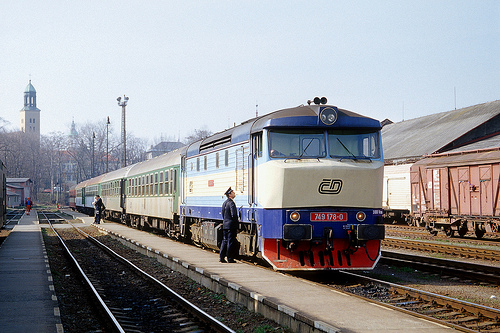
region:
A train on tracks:
[74, 99, 390, 280]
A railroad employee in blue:
[215, 181, 247, 270]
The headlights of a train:
[282, 196, 371, 227]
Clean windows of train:
[267, 120, 381, 167]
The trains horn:
[302, 91, 328, 109]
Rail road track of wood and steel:
[377, 278, 472, 329]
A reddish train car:
[409, 151, 495, 228]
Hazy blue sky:
[199, 37, 336, 80]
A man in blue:
[87, 194, 109, 227]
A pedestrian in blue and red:
[22, 197, 34, 217]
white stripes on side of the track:
[233, 284, 287, 309]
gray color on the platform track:
[250, 266, 294, 294]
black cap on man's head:
[203, 184, 238, 204]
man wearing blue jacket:
[193, 187, 256, 231]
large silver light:
[96, 82, 143, 177]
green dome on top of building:
[15, 77, 54, 101]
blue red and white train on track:
[211, 95, 406, 287]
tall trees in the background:
[55, 118, 128, 158]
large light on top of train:
[272, 93, 362, 133]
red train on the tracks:
[390, 145, 487, 211]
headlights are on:
[284, 205, 382, 235]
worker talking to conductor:
[201, 181, 256, 277]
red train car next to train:
[411, 146, 497, 264]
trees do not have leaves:
[37, 131, 104, 177]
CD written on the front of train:
[306, 167, 363, 204]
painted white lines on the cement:
[153, 237, 297, 330]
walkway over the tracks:
[27, 205, 101, 241]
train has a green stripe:
[79, 167, 185, 220]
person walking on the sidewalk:
[13, 186, 50, 219]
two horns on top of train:
[297, 91, 331, 105]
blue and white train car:
[133, 100, 410, 285]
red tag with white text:
[305, 202, 360, 227]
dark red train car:
[404, 151, 489, 216]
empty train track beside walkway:
[30, 197, 185, 330]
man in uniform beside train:
[215, 176, 249, 265]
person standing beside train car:
[85, 186, 111, 227]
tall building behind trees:
[22, 76, 47, 151]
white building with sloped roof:
[382, 113, 493, 205]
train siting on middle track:
[51, 100, 409, 278]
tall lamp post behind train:
[107, 90, 139, 164]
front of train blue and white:
[175, 108, 427, 318]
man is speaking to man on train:
[213, 184, 243, 255]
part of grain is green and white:
[76, 165, 177, 222]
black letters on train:
[310, 165, 342, 194]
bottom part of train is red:
[265, 237, 394, 279]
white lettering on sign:
[311, 201, 348, 226]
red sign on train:
[308, 203, 350, 226]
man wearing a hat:
[215, 179, 242, 204]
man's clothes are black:
[210, 189, 244, 257]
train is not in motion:
[49, 66, 423, 284]